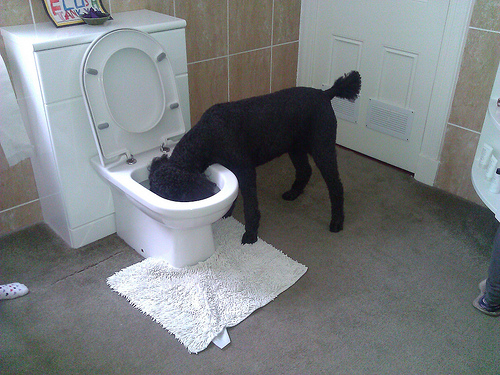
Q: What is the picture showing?
A: It is showing a bathroom.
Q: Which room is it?
A: It is a bathroom.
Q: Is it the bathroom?
A: Yes, it is the bathroom.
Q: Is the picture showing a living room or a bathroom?
A: It is showing a bathroom.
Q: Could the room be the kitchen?
A: No, it is the bathroom.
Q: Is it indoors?
A: Yes, it is indoors.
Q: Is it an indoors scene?
A: Yes, it is indoors.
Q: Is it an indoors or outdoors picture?
A: It is indoors.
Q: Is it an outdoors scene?
A: No, it is indoors.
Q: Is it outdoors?
A: No, it is indoors.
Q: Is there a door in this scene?
A: Yes, there is a door.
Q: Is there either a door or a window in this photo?
A: Yes, there is a door.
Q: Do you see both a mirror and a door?
A: No, there is a door but no mirrors.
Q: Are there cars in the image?
A: No, there are no cars.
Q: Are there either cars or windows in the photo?
A: No, there are no cars or windows.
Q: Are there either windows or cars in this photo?
A: No, there are no cars or windows.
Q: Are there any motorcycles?
A: No, there are no motorcycles.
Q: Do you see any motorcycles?
A: No, there are no motorcycles.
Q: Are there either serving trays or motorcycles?
A: No, there are no motorcycles or serving trays.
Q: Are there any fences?
A: No, there are no fences.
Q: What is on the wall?
A: The tiles are on the wall.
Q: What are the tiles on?
A: The tiles are on the wall.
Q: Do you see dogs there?
A: Yes, there is a dog.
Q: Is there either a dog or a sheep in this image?
A: Yes, there is a dog.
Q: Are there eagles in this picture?
A: No, there are no eagles.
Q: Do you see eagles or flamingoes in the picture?
A: No, there are no eagles or flamingoes.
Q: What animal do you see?
A: The animal is a dog.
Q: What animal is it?
A: The animal is a dog.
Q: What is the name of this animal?
A: This is a dog.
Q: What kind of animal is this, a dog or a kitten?
A: This is a dog.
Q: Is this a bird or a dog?
A: This is a dog.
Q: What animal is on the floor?
A: The dog is on the floor.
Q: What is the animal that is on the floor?
A: The animal is a dog.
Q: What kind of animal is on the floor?
A: The animal is a dog.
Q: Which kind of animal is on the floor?
A: The animal is a dog.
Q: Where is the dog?
A: The dog is on the floor.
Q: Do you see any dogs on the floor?
A: Yes, there is a dog on the floor.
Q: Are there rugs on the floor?
A: No, there is a dog on the floor.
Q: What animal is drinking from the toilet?
A: The animal is a dog.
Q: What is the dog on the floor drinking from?
A: The dog is drinking from the toilet.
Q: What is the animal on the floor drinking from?
A: The dog is drinking from the toilet.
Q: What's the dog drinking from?
A: The dog is drinking from the toilet.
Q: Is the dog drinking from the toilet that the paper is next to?
A: Yes, the dog is drinking from the toilet.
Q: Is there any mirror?
A: No, there are no mirrors.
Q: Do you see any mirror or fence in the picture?
A: No, there are no mirrors or fences.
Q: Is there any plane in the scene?
A: No, there are no airplanes.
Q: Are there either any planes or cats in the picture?
A: No, there are no planes or cats.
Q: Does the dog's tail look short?
A: Yes, the tail is short.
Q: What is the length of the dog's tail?
A: The tail is short.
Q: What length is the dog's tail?
A: The tail is short.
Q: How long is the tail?
A: The tail is short.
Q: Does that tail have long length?
A: No, the tail is short.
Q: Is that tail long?
A: No, the tail is short.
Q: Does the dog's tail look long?
A: No, the tail is short.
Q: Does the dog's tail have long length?
A: No, the tail is short.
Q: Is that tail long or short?
A: The tail is short.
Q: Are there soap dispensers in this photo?
A: No, there are no soap dispensers.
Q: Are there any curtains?
A: No, there are no curtains.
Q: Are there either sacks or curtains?
A: No, there are no curtains or sacks.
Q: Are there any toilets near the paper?
A: Yes, there is a toilet near the paper.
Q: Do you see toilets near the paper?
A: Yes, there is a toilet near the paper.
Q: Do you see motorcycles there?
A: No, there are no motorcycles.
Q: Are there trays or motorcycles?
A: No, there are no motorcycles or trays.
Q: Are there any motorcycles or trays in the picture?
A: No, there are no motorcycles or trays.